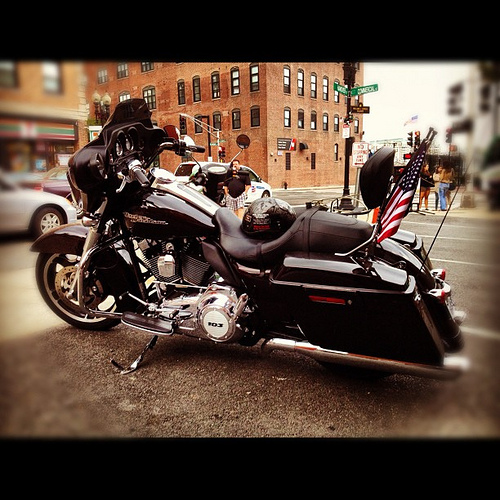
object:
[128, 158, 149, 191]
handle bars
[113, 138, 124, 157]
gauges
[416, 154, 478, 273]
antenna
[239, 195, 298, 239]
helmet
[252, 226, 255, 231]
letter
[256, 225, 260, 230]
letter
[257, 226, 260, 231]
letter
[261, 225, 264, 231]
letter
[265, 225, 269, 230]
letter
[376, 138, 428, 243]
flag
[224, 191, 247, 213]
shorts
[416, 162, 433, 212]
person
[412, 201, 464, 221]
corner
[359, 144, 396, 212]
back rest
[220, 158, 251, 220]
man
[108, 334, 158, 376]
stand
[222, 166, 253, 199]
shirt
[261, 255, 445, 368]
side compartment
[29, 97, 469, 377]
motorcycle